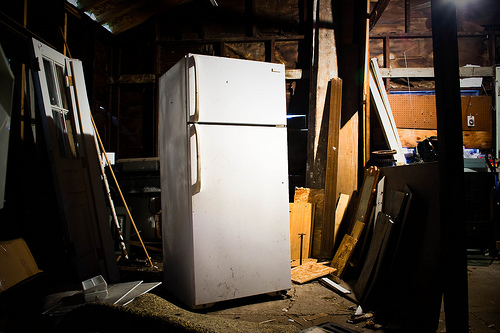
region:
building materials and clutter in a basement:
[5, 5, 494, 326]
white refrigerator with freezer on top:
[155, 54, 296, 309]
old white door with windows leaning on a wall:
[24, 34, 119, 263]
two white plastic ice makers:
[79, 273, 111, 305]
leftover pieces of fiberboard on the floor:
[292, 218, 363, 286]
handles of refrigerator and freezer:
[183, 52, 202, 199]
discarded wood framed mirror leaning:
[352, 164, 382, 231]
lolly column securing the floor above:
[426, 0, 472, 332]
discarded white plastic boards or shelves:
[59, 275, 160, 312]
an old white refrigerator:
[160, 53, 290, 305]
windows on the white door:
[29, 38, 81, 163]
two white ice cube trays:
[82, 275, 109, 298]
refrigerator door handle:
[189, 124, 201, 194]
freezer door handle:
[187, 54, 199, 121]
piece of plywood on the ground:
[290, 259, 338, 282]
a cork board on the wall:
[390, 93, 492, 128]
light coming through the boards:
[67, 0, 112, 35]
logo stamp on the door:
[266, 66, 283, 73]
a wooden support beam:
[432, 1, 469, 331]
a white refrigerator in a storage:
[155, 50, 292, 310]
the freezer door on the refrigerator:
[185, 53, 286, 123]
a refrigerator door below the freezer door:
[185, 123, 292, 305]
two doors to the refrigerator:
[186, 52, 293, 307]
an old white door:
[30, 36, 119, 275]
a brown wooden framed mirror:
[353, 164, 378, 220]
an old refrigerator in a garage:
[153, 53, 292, 310]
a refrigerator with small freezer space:
[186, 52, 291, 307]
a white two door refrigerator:
[156, 52, 292, 309]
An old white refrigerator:
[155, 53, 294, 310]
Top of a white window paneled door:
[26, 35, 87, 144]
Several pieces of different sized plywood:
[288, 165, 369, 286]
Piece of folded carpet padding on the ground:
[126, 291, 296, 331]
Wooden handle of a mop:
[88, 113, 156, 268]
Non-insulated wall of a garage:
[208, 2, 493, 90]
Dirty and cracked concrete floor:
[205, 280, 377, 325]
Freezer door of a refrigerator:
[184, 51, 288, 126]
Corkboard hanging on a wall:
[390, 92, 492, 130]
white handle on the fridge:
[163, 49, 231, 202]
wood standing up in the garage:
[288, 55, 393, 311]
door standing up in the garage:
[20, 25, 148, 305]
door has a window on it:
[36, 48, 121, 198]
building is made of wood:
[88, 9, 179, 169]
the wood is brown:
[81, 43, 170, 153]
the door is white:
[33, 37, 133, 245]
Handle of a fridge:
[186, 123, 206, 196]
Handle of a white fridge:
[188, 124, 207, 199]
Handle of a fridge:
[187, 53, 204, 124]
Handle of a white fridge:
[186, 53, 205, 125]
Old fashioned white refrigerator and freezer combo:
[158, 55, 292, 312]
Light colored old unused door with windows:
[27, 38, 124, 283]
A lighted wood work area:
[287, 0, 494, 312]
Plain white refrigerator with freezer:
[155, 52, 295, 306]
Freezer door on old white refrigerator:
[183, 50, 290, 125]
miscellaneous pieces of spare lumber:
[293, 82, 425, 307]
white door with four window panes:
[23, 37, 123, 260]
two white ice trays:
[79, 273, 111, 305]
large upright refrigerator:
[155, 54, 292, 309]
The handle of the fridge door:
[192, 122, 204, 197]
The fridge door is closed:
[189, 122, 296, 305]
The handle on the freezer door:
[188, 54, 203, 120]